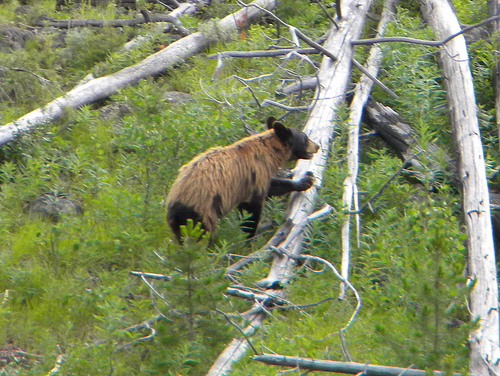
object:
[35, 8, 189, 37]
tree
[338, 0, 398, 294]
log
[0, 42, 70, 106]
tree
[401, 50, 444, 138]
tree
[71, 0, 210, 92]
tree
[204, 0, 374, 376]
tree trunk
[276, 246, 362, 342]
branches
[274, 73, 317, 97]
branches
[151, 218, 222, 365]
short pine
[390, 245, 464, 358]
short pine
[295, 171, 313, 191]
paws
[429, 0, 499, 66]
log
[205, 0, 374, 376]
tree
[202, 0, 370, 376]
log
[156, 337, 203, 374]
plant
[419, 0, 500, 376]
log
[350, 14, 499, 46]
branch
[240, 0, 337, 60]
branch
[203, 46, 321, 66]
branch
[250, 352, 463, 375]
branch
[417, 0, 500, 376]
tree trunk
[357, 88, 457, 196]
tree trunk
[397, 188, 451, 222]
plant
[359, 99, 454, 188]
log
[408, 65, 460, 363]
weed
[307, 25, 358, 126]
woods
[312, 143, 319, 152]
nose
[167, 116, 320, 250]
bear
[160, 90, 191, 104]
stone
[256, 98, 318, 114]
branch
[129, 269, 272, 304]
branches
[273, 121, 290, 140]
ear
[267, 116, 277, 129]
ear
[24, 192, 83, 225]
rock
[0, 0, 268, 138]
woods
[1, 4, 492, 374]
ground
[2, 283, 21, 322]
plant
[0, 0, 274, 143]
tree